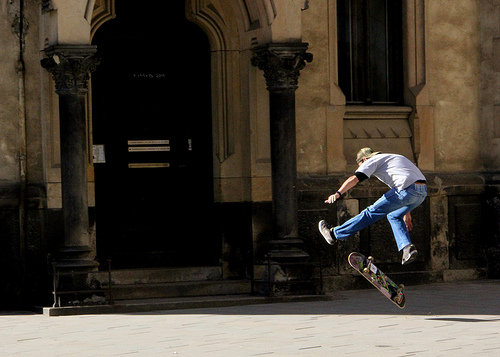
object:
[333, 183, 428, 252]
blue jeans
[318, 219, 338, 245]
sneaker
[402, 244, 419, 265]
sneaker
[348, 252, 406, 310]
skate board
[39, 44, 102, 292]
pillar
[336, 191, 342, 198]
black band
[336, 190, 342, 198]
left wrist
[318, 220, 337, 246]
foot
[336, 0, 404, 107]
window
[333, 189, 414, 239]
leg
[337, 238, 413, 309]
blue backpack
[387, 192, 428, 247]
leg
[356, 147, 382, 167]
head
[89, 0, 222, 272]
doorway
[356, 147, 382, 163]
hat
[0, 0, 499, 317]
building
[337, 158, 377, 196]
arm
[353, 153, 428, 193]
shirt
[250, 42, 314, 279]
pillar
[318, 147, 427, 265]
man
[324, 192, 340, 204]
hand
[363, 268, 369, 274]
wheel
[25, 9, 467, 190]
air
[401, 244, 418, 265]
foot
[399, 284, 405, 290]
wheel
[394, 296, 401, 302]
wheel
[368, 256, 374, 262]
wheel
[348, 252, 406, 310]
bottom